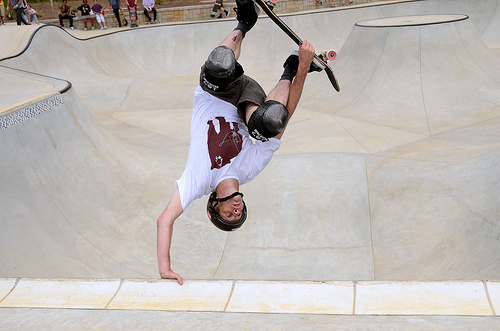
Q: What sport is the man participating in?
A: Skateboarding.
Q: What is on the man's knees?
A: Knee pads.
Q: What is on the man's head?
A: Helmet.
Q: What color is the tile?
A: White.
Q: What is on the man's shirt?
A: Brown bear.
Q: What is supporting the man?
A: His left hand.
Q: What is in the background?
A: Spectators.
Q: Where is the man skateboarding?
A: Skate park.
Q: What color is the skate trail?
A: White.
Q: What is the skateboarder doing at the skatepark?
A: Tricks.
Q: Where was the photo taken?
A: In a skatepark.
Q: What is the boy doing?
A: Skating.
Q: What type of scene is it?
A: Outdoor scene.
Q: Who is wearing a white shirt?
A: The boy.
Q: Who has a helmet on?
A: The boy.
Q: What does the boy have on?
A: Guards.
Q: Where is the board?
A: In the air.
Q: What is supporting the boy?
A: Hand.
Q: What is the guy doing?
A: A trick.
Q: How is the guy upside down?
A: Holding the edge.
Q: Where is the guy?
A: A ramp.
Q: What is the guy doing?
A: Skateboarding.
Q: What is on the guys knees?
A: Knee pads.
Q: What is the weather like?
A: Sunny.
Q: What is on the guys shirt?
A: Brown design.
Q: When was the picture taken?
A: Day time.